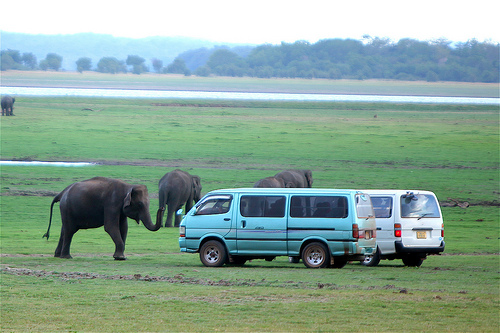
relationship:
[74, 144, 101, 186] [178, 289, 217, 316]
water in grass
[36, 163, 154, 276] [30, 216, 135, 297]
elephant has leg